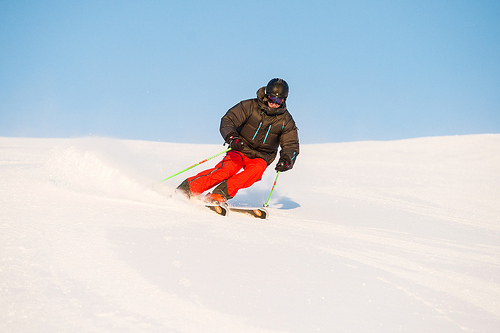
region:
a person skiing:
[167, 76, 314, 223]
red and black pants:
[186, 147, 269, 199]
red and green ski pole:
[152, 146, 229, 186]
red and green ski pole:
[263, 168, 283, 208]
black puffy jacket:
[217, 86, 299, 173]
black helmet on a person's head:
[265, 78, 290, 98]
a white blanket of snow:
[1, 132, 498, 332]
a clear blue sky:
[1, 2, 498, 135]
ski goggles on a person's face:
[261, 90, 290, 104]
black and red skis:
[198, 201, 270, 221]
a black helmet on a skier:
[267, 77, 292, 105]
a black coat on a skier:
[225, 86, 306, 169]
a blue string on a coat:
[261, 120, 271, 145]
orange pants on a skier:
[174, 148, 274, 202]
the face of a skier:
[266, 90, 283, 111]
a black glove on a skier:
[273, 156, 286, 172]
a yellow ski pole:
[165, 139, 239, 182]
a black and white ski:
[228, 202, 269, 219]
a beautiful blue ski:
[5, 3, 496, 129]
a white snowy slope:
[0, 140, 495, 329]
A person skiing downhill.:
[169, 64, 313, 236]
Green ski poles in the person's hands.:
[148, 132, 298, 217]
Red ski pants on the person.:
[169, 148, 271, 214]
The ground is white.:
[1, 117, 496, 330]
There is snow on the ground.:
[14, 121, 493, 329]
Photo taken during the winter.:
[0, 3, 495, 328]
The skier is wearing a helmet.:
[259, 76, 290, 107]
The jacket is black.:
[211, 86, 301, 175]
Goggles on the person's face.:
[262, 93, 292, 107]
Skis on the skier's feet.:
[178, 181, 271, 228]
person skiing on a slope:
[156, 64, 306, 228]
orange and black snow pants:
[168, 143, 265, 207]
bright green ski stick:
[150, 146, 229, 183]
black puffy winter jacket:
[210, 91, 305, 168]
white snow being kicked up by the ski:
[50, 141, 192, 206]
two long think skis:
[204, 200, 268, 221]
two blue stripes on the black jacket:
[249, 120, 276, 147]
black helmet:
[259, 76, 292, 109]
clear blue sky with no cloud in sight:
[1, 0, 499, 142]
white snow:
[2, 139, 499, 331]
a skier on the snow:
[69, 32, 380, 259]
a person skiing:
[117, 35, 390, 312]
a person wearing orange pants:
[161, 11, 363, 258]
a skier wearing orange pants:
[166, 65, 387, 261]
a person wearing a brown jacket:
[210, 42, 333, 181]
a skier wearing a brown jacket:
[166, 52, 316, 184]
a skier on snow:
[136, 35, 358, 238]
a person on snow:
[137, 52, 388, 277]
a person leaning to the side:
[148, 70, 389, 253]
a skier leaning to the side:
[146, 64, 376, 251]